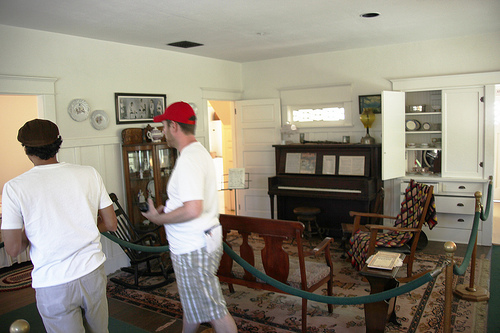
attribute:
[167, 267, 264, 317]
shorts — white, gray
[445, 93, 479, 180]
cabinet — white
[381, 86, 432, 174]
cabinet — white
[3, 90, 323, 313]
men — standing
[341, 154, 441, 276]
wood chair — rocking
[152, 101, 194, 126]
hat — red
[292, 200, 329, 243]
stool — wooden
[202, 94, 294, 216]
door — open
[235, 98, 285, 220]
white door — wooden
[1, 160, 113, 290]
t shirt — white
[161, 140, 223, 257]
t shirt — white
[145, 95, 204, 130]
hat — red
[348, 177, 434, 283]
rocking chair — wooden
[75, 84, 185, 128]
picture — framed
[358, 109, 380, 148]
cup — glass, yellow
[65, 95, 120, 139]
plates — decorative, white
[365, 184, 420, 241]
blanket — colorful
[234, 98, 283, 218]
door — wooden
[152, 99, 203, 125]
cap — red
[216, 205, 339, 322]
bench — wooden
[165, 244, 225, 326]
shorts — plaid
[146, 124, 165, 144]
tea kettle — vintage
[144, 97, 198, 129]
cap — red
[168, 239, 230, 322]
shorts — plaid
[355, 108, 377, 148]
lamp — vintage, kerosene, yellow, glass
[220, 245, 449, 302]
rope — green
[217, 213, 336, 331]
bench — brown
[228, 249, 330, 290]
cushion — tan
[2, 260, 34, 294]
rug — oval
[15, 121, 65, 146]
brown hat — round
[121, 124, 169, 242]
curio cabinet — glass, wood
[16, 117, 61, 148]
hat — brown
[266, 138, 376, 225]
piano — brown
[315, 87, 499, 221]
cupboard — white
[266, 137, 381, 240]
piano — upright, wooden, dark, vintage, black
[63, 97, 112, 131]
plates — white